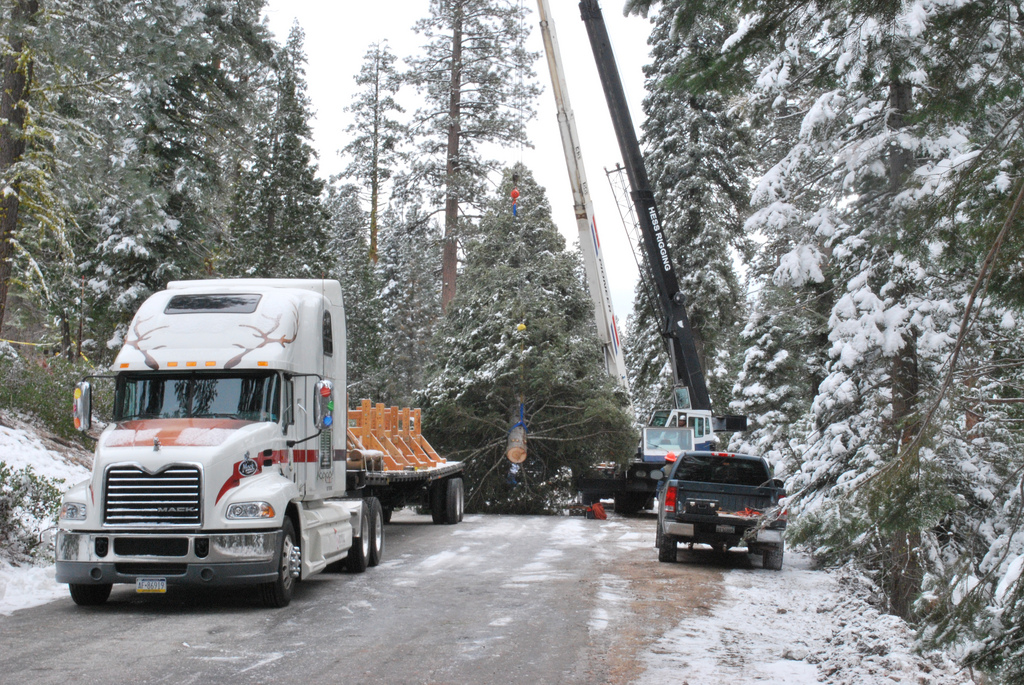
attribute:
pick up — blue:
[658, 447, 789, 568]